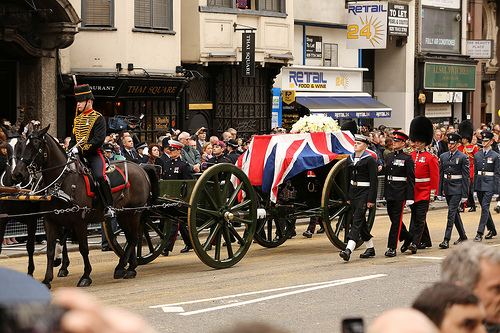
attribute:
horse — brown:
[13, 118, 163, 294]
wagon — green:
[161, 128, 380, 268]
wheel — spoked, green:
[321, 156, 378, 252]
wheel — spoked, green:
[187, 161, 260, 268]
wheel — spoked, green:
[103, 205, 174, 267]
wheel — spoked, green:
[247, 185, 297, 248]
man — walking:
[338, 131, 380, 262]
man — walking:
[381, 128, 416, 257]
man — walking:
[404, 115, 441, 255]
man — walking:
[437, 131, 472, 249]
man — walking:
[471, 128, 499, 245]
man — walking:
[156, 138, 196, 258]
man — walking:
[201, 139, 236, 252]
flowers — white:
[288, 113, 343, 136]